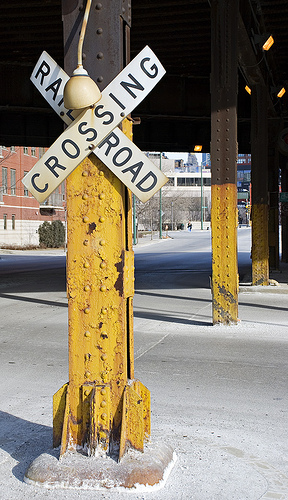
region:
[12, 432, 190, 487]
base of a metal pole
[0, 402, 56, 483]
shadow casted on the ground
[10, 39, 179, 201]
railroad crossing on a pole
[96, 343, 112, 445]
rivets on a pole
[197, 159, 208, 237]
metal pole on the street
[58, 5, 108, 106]
lamp hanging from a pole above crossing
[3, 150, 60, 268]
building on side of road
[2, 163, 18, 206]
windows on a building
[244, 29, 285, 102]
illuminated lights on ceiling of overpass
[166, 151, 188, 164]
hazy sky in the distance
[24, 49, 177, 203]
white sign with black letters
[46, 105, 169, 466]
a painted yellow pole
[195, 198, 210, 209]
a green and white sign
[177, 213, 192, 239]
a person walking on sidewalk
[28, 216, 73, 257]
two bushes buy a building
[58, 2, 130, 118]
a light coming in front of sign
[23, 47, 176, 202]
a sign indicating railroad crossing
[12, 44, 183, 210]
a black and white sign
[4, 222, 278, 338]
shadow on ground from poles and bridge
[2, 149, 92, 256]
a red brick building with white on the bottom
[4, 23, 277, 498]
a scene outside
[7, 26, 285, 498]
a scene at a railroad crossing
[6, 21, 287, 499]
a scene during the day time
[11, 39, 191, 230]
a railroad crossing sign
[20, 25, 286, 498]
a row of yellow steel beams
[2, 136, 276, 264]
buildings in the background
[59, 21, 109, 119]
a white street light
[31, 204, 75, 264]
a green bush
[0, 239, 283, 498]
a gray pavement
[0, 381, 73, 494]
a shadow on ground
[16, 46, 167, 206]
a sign is mounted to the post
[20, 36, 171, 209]
the sign is a rail road crossing sign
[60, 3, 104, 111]
a light hangs above the sign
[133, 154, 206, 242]
trees are in the background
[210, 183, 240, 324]
the bottom portion of the pole is yellow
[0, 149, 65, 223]
a red building is in the background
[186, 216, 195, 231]
two people are in the background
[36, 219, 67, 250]
green shrubs are in front of the building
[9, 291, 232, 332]
the post casts a shadow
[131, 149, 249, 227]
few buildings are in the background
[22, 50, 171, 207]
black and white railroad crossing sign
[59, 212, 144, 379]
yellow painted metal support post with bolts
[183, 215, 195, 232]
person in jeans walking in the distance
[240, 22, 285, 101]
illuminated street lights under the bridge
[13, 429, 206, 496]
cement support for metal post holding up sign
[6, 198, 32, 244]
brick and cement style red and gray building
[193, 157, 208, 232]
green post with green street sign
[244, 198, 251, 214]
traffic light for vehicles in the distance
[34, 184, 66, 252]
shrub growing under balcony of building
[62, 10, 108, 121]
light hanging over railroad crossing sign